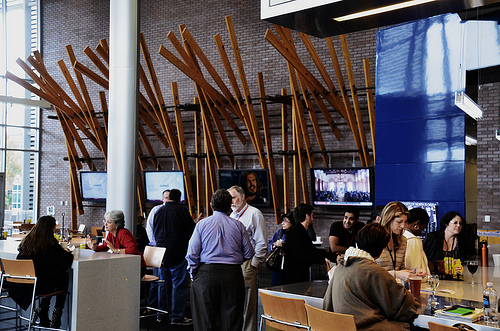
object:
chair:
[260, 291, 308, 330]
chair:
[305, 303, 358, 330]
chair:
[0, 257, 64, 330]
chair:
[139, 245, 168, 323]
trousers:
[191, 265, 243, 330]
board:
[376, 13, 465, 218]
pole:
[104, 2, 140, 228]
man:
[184, 190, 256, 330]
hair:
[207, 189, 231, 215]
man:
[152, 188, 196, 326]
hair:
[169, 189, 182, 203]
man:
[226, 186, 268, 330]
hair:
[226, 185, 245, 194]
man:
[283, 203, 317, 285]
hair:
[293, 202, 313, 222]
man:
[329, 208, 366, 254]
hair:
[344, 207, 360, 222]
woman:
[19, 215, 73, 294]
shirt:
[17, 242, 73, 292]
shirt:
[153, 202, 194, 268]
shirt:
[279, 222, 317, 279]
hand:
[189, 269, 202, 281]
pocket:
[188, 274, 200, 300]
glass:
[466, 261, 478, 286]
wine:
[467, 260, 478, 274]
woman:
[85, 210, 147, 278]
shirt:
[95, 229, 145, 268]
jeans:
[156, 262, 187, 318]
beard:
[308, 215, 314, 228]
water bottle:
[483, 281, 497, 324]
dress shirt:
[228, 204, 268, 268]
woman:
[319, 221, 416, 330]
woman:
[377, 201, 408, 272]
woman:
[431, 212, 466, 264]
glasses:
[102, 218, 114, 224]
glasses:
[448, 220, 463, 224]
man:
[242, 170, 262, 199]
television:
[215, 170, 272, 211]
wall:
[39, 0, 376, 248]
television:
[80, 170, 109, 200]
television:
[144, 171, 189, 207]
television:
[309, 166, 374, 211]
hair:
[16, 216, 59, 262]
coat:
[322, 256, 420, 330]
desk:
[259, 258, 499, 329]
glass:
[426, 276, 439, 307]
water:
[427, 275, 438, 289]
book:
[432, 305, 484, 321]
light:
[454, 87, 483, 119]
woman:
[270, 210, 306, 284]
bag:
[264, 246, 282, 269]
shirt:
[328, 222, 367, 261]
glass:
[409, 275, 421, 299]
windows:
[1, 1, 40, 231]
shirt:
[183, 212, 255, 265]